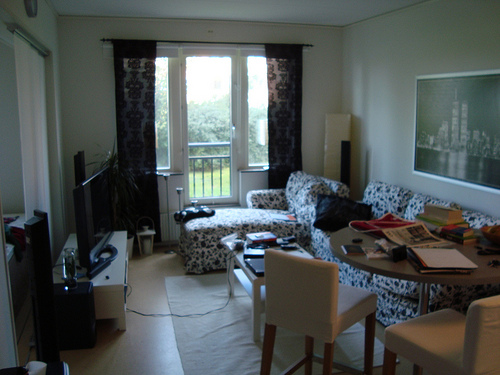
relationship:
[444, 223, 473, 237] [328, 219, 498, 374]
books on table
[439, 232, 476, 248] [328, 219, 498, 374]
books on table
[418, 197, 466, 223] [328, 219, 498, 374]
books on table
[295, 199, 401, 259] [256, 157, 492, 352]
pillow on sofa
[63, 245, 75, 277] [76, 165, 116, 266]
vase beside screen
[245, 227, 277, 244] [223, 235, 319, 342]
book on table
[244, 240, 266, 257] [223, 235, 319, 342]
book on table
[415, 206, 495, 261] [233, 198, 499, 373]
books on table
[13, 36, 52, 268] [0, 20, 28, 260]
curtain on side window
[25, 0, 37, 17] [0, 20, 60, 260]
round clock above side window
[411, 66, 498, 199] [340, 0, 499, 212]
framed art on wall